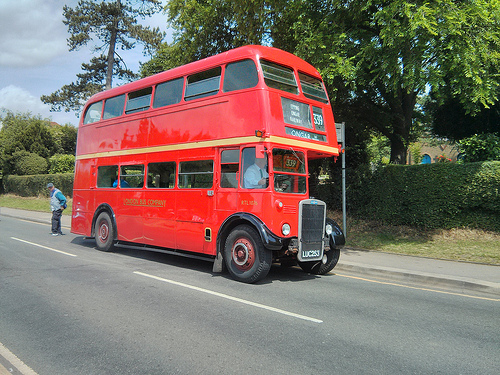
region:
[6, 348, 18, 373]
double line on the road.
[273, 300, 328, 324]
broken line on the road.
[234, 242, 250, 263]
hubcap on the tire.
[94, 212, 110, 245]
right rear tire of bus.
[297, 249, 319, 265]
license plate on the bus.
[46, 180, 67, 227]
person standing behind the bus.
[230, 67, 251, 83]
window on the bus.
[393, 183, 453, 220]
shadow on the bushes.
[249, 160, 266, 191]
driver of the bus.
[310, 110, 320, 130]
number on the bus.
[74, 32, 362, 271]
A double decker bus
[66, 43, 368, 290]
A red bus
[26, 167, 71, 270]
A man trying to cross the street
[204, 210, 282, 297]
A bus wheel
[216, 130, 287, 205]
A male bus driver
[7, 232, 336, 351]
White broken lines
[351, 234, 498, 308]
A sidewalk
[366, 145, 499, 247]
Green hedges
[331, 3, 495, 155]
A tree with leaves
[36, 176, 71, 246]
A man with a blue shirt and gray vest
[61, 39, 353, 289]
the bus is red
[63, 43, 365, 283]
the bus is a double decker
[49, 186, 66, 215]
the man is wearing a grey vest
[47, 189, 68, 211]
the man is wearing a blue shirt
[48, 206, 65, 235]
the man is wearing black pants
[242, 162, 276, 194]
the bus driver is wearing a white shirt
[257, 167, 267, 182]
the driver is wearing a black tie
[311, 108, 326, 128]
the bus is number 339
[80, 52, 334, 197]
the bus has many windows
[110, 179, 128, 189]
the man on the bus is wearing a blue shirt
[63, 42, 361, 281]
double decker bus on street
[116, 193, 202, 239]
gold words on red body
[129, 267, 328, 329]
white line in road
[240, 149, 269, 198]
driver in front of bus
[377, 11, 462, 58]
green leaves on tree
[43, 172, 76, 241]
man walking behind bus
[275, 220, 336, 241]
headlights on front of bus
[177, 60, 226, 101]
open window on bus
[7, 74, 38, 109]
white cloud in daytime sky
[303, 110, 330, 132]
number on front of bus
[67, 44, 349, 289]
a bus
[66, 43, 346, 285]
a double decker bus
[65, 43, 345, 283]
the double decker bus is red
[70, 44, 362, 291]
the bus is on the road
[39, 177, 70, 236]
a man walks behind the bus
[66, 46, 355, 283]
the windows on the bus are open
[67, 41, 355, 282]
the bus is number 339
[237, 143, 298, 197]
a man in a white shirt is driving the bus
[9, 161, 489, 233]
bushes are alongside the road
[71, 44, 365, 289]
people are on the bus